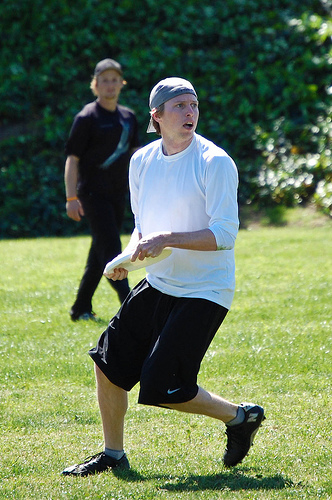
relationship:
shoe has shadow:
[223, 399, 264, 467] [155, 475, 287, 494]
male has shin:
[63, 77, 263, 480] [162, 406, 240, 421]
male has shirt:
[63, 77, 263, 480] [104, 129, 239, 309]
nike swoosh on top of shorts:
[165, 385, 182, 395] [89, 279, 229, 407]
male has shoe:
[63, 77, 263, 480] [223, 399, 264, 467]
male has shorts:
[63, 77, 263, 480] [89, 279, 229, 407]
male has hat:
[63, 77, 263, 480] [148, 74, 196, 134]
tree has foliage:
[2, 2, 331, 239] [2, 1, 328, 236]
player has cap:
[64, 58, 137, 315] [93, 58, 121, 78]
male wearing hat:
[63, 77, 263, 480] [148, 74, 196, 134]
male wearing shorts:
[63, 77, 263, 480] [89, 279, 229, 407]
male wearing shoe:
[63, 77, 263, 480] [223, 399, 264, 467]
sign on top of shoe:
[248, 412, 259, 424] [223, 399, 264, 467]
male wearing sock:
[63, 77, 263, 480] [229, 406, 248, 428]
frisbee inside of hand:
[104, 244, 173, 280] [102, 268, 127, 281]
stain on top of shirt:
[217, 245, 233, 250] [104, 129, 239, 309]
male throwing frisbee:
[63, 77, 263, 480] [104, 244, 173, 280]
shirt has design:
[66, 101, 139, 205] [99, 119, 133, 167]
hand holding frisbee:
[102, 268, 127, 281] [104, 244, 173, 280]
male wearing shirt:
[63, 77, 263, 480] [104, 129, 239, 309]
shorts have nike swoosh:
[89, 279, 229, 407] [165, 385, 182, 395]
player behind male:
[64, 58, 137, 315] [63, 77, 263, 480]